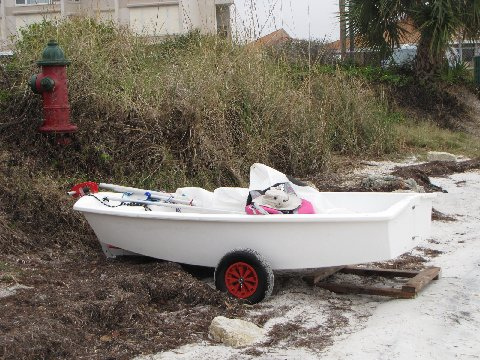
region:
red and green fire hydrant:
[26, 36, 84, 145]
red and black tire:
[207, 253, 283, 303]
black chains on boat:
[103, 200, 157, 226]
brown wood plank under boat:
[300, 261, 446, 309]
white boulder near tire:
[215, 314, 272, 358]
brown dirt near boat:
[67, 279, 170, 351]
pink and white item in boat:
[232, 131, 322, 240]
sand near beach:
[447, 194, 459, 312]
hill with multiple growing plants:
[82, 28, 401, 139]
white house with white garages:
[49, 6, 260, 51]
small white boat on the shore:
[63, 160, 442, 305]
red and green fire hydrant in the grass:
[25, 36, 82, 156]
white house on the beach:
[326, 7, 479, 79]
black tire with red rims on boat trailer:
[212, 247, 276, 309]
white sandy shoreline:
[147, 148, 476, 359]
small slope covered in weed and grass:
[4, 6, 474, 187]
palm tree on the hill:
[349, 3, 477, 85]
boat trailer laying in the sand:
[87, 234, 445, 300]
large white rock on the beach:
[204, 311, 274, 351]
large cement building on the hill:
[1, 2, 235, 66]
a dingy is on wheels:
[63, 158, 437, 309]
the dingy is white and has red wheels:
[72, 169, 435, 307]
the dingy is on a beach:
[75, 158, 478, 358]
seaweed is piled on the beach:
[5, 258, 191, 354]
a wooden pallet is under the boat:
[311, 262, 442, 300]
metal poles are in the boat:
[91, 177, 228, 211]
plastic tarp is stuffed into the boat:
[177, 163, 318, 225]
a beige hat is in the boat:
[247, 186, 303, 216]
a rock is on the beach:
[201, 308, 296, 354]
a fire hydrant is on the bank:
[25, 35, 87, 141]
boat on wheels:
[194, 211, 281, 315]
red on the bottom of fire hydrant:
[31, 69, 100, 130]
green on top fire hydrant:
[33, 33, 96, 61]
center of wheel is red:
[231, 263, 263, 298]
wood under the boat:
[337, 259, 447, 323]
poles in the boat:
[145, 163, 214, 220]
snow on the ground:
[432, 285, 449, 359]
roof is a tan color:
[259, 20, 266, 51]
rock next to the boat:
[188, 302, 242, 354]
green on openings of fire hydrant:
[24, 66, 56, 92]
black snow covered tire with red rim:
[211, 248, 278, 306]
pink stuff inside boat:
[238, 191, 323, 230]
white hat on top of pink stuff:
[252, 185, 308, 219]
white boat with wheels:
[78, 182, 435, 300]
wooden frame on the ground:
[302, 258, 443, 300]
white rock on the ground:
[204, 314, 269, 350]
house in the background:
[0, 1, 244, 70]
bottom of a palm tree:
[339, 0, 475, 93]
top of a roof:
[239, 30, 309, 59]